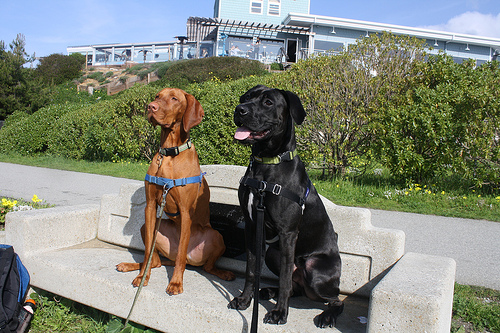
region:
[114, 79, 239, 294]
Brown dog next to black dog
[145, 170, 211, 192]
Blue harness on dog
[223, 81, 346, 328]
Black dog on cement bench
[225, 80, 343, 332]
Black dog has tongue out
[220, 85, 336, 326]
Black dog has black harness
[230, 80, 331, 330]
Black dog has green collar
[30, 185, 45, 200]
Flower is yellow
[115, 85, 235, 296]
Brown dog on cement bench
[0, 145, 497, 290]
Sidewalk behind dogs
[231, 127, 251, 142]
Tongue is pink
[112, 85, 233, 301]
brown dog sitting on a concrete bench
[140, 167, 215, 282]
dog harness attached to a rope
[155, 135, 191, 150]
collar around the brown dog's neck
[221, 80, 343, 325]
black dog on a concrete bench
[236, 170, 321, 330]
black harness on a black dog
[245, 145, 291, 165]
green collar around the black dog's neck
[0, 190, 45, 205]
yellow flowers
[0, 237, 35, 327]
blue and black backpack on the ground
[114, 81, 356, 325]
two dogs on a concrete bench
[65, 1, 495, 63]
large light blue building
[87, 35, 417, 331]
two dogs sitting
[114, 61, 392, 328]
a black and brown dog sitting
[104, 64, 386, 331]
two dogs sitting on bench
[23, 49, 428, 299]
two dogs sitting on cement bench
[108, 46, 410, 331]
dogs sitting on cement bench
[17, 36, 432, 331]
two dogs sitting outside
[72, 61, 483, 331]
dogs that are sitting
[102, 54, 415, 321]
dogs that are sitting outside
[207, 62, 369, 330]
a black dog with a black harness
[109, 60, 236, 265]
a brown dog with a blue harness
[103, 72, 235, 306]
The dog is sitting.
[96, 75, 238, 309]
The dog is wearing a collar.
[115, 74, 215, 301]
The dog is on a leash.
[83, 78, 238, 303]
The dog is brown.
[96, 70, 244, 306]
The dog is short-haired.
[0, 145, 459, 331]
The bench is concrete.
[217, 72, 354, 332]
The dog is black.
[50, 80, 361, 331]
Two dogs sitting together on a bench.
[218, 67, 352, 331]
The dogs tongue is hanging out.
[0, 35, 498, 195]
The bushes are green.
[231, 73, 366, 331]
black dog sitting on a bench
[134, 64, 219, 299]
brown dog sitting on a bench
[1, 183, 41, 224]
yellow flower blooms along edge of side walk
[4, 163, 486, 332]
cement bench in the park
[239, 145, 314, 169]
green canvas dog collar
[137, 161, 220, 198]
light blue dog collar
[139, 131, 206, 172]
gray dog collar with plastic adjusters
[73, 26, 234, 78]
building on top of hillside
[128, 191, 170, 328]
brown leash attached to collar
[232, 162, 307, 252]
black canvas harness with black leash